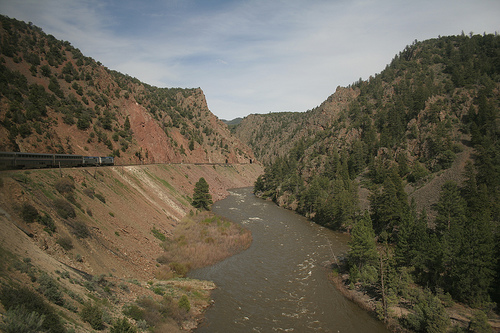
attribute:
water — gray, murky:
[187, 184, 375, 312]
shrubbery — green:
[195, 177, 213, 211]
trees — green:
[1, 16, 139, 154]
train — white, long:
[1, 149, 114, 167]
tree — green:
[193, 177, 212, 210]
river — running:
[187, 183, 369, 311]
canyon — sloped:
[4, 14, 268, 312]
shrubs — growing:
[193, 178, 212, 211]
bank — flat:
[178, 204, 253, 313]